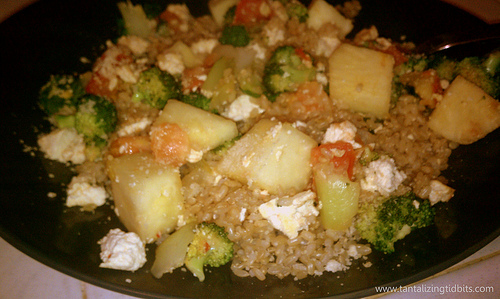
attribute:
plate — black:
[1, 1, 494, 298]